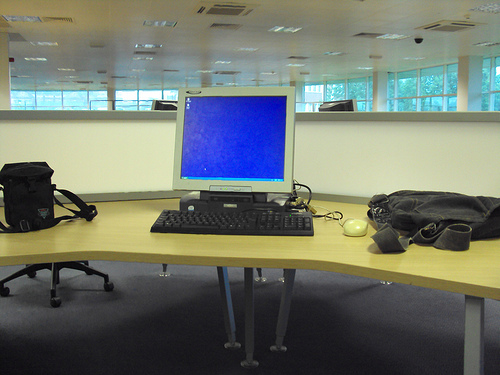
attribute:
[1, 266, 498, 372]
floor — gray, carpet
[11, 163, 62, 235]
bag — black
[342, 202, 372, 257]
mouse — white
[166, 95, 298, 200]
monitor — white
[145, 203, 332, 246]
keyboard — black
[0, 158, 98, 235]
bag — black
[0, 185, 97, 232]
strap — black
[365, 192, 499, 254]
bag — black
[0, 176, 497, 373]
desk — wooden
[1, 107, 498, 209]
dividing wall — white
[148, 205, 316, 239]
computer keyboard — black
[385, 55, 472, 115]
windows — clear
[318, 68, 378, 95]
windows — clear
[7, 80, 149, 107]
windows — clear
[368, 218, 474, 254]
straps — black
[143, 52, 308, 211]
monitor — blue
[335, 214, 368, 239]
mouse — white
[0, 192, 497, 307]
desk — wooden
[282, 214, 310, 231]
keypad — numeric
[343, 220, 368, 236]
mouse — white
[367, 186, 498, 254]
bag — black